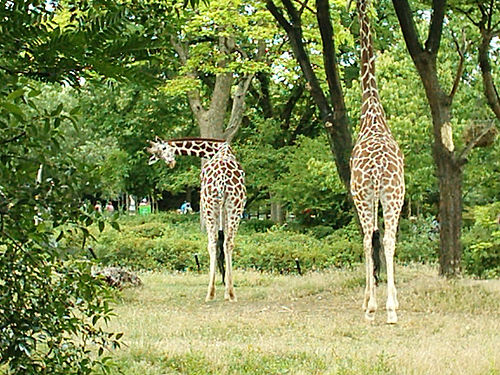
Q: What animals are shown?
A: Giraffes.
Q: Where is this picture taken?
A: The bush.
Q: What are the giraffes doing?
A: Standing.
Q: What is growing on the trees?
A: Leaves.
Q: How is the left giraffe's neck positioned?
A: To the left.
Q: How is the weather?
A: Sunny.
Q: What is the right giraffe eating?
A: Leaves.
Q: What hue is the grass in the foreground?
A: Brown.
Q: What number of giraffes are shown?
A: Two.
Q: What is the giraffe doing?
A: Looking backwards.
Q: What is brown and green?
A: Grass.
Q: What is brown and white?
A: Giraffes.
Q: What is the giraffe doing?
A: Cranes its neck left and back.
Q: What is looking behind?
A: Giraffe.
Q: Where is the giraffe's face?
A: Up in the trees.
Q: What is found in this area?
A: Bushes and trees.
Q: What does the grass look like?
A: Green and dry.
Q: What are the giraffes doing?
A: Standing.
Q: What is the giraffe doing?
A: Looking back.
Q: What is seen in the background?
A: Trees.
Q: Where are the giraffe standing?
A: In a grassy field.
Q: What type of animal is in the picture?
A: Giraffe.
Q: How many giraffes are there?
A: Two.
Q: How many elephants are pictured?
A: Zero.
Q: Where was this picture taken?
A: In a zoo.